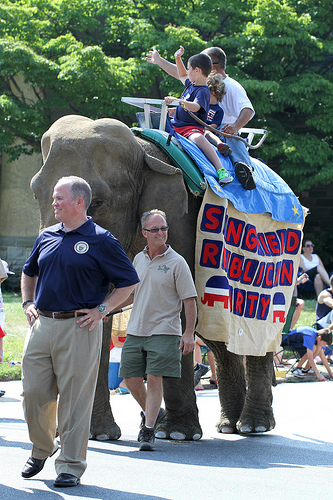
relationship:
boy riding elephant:
[163, 44, 234, 190] [35, 112, 313, 453]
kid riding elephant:
[197, 69, 232, 158] [35, 112, 313, 453]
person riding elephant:
[140, 39, 257, 187] [35, 112, 313, 453]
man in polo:
[19, 174, 140, 490] [17, 214, 138, 319]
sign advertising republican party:
[187, 177, 312, 358] [198, 206, 305, 318]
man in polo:
[120, 208, 198, 450] [119, 245, 200, 340]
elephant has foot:
[35, 112, 313, 453] [156, 413, 205, 440]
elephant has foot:
[35, 112, 313, 453] [238, 403, 277, 437]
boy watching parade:
[282, 325, 332, 378] [17, 43, 332, 491]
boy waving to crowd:
[159, 44, 236, 181] [278, 241, 332, 378]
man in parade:
[19, 174, 141, 490] [17, 43, 332, 491]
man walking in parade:
[19, 174, 141, 490] [17, 43, 332, 491]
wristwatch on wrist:
[98, 301, 108, 319] [97, 301, 110, 319]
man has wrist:
[19, 174, 140, 490] [97, 301, 110, 319]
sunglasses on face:
[147, 221, 172, 233] [146, 214, 171, 249]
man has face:
[120, 208, 198, 450] [146, 214, 171, 249]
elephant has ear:
[35, 112, 313, 453] [139, 153, 189, 219]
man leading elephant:
[117, 208, 198, 451] [35, 112, 313, 453]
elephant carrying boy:
[35, 112, 313, 453] [163, 44, 234, 190]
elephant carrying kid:
[35, 112, 313, 453] [197, 72, 232, 153]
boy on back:
[163, 44, 234, 190] [144, 123, 302, 205]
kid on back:
[197, 72, 232, 153] [144, 123, 302, 205]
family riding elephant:
[146, 38, 275, 189] [35, 112, 313, 453]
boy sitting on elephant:
[163, 44, 234, 190] [35, 112, 313, 453]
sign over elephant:
[187, 177, 312, 358] [35, 112, 313, 453]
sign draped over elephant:
[187, 177, 312, 358] [35, 112, 313, 453]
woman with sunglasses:
[295, 236, 332, 309] [302, 243, 316, 251]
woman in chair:
[295, 236, 332, 309] [296, 273, 331, 302]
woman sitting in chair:
[295, 236, 332, 309] [296, 273, 331, 302]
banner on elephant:
[180, 191, 312, 364] [35, 112, 313, 453]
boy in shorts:
[159, 44, 236, 181] [171, 120, 204, 138]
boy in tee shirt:
[159, 44, 236, 181] [169, 75, 220, 128]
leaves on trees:
[4, 0, 331, 201] [5, 0, 332, 226]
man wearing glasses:
[120, 208, 198, 450] [149, 221, 172, 230]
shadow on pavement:
[2, 397, 333, 489] [0, 356, 332, 494]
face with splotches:
[50, 177, 93, 224] [61, 201, 82, 217]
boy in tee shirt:
[282, 325, 332, 378] [280, 328, 324, 351]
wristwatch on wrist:
[100, 301, 108, 319] [97, 301, 110, 319]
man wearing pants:
[19, 174, 141, 490] [19, 314, 114, 473]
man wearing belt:
[19, 174, 141, 490] [37, 307, 90, 319]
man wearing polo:
[19, 174, 141, 490] [17, 214, 141, 319]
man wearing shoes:
[19, 174, 141, 490] [23, 443, 90, 488]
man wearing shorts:
[117, 208, 198, 451] [116, 332, 183, 380]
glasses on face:
[149, 221, 172, 230] [146, 214, 171, 249]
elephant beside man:
[35, 112, 313, 453] [19, 174, 141, 490]